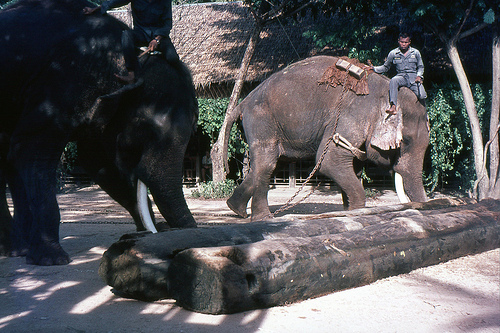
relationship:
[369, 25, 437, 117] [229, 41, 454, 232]
man sitting on elephant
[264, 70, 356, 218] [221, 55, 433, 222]
chain attached elephant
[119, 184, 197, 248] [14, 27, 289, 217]
tusk on elephant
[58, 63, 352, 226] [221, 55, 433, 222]
chain on elephant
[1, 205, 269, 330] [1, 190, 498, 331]
shadow on ground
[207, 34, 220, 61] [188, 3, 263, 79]
straw for roof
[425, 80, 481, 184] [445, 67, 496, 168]
bush behind tree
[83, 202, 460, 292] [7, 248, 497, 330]
poles on dirt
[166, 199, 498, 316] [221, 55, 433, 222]
tree log laying near elephant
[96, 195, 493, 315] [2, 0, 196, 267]
log laying near elephant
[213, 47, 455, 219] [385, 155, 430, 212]
elephant has tusk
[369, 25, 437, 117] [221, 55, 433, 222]
man sitting on elephant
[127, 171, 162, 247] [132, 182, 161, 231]
elephant has task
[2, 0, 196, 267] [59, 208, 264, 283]
elephant in shade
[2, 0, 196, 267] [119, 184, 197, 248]
elephant has tusk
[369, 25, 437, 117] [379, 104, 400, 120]
man wears shoes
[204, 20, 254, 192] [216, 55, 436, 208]
tree behind elephant